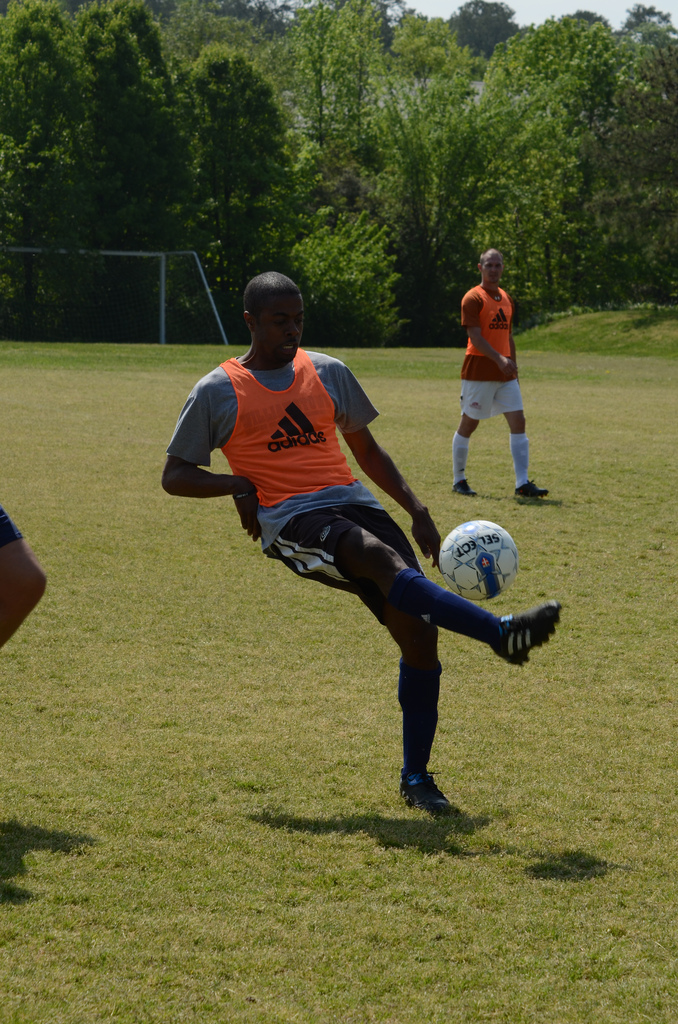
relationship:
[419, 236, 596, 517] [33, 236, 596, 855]
man walking on field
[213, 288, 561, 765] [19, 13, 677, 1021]
man playing soccer